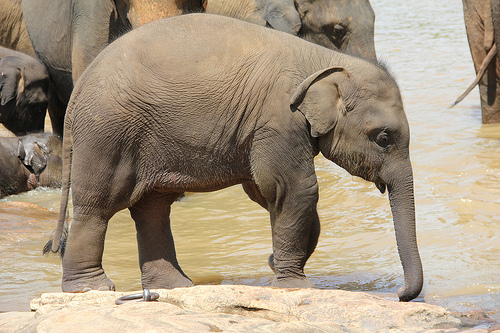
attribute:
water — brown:
[0, 0, 498, 332]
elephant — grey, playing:
[0, 127, 68, 200]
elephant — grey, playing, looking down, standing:
[1, 47, 49, 134]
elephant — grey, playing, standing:
[19, 0, 209, 138]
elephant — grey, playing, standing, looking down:
[201, 0, 381, 74]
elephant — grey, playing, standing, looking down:
[51, 12, 425, 303]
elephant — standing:
[450, 0, 500, 126]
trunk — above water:
[375, 156, 428, 302]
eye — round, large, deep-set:
[381, 131, 389, 146]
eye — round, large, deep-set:
[332, 24, 347, 42]